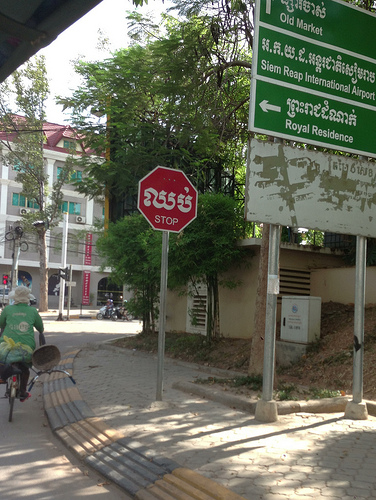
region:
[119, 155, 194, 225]
red and white sign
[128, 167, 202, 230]
white characters on sign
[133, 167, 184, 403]
sign on grey pole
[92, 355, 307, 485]
sidewalk is light grey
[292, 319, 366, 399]
light brown mulch on hill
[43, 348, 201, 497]
grey and yellow curb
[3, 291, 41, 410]
man is on bike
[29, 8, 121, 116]
grey and bright sky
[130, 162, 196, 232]
red and white sign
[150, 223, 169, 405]
stop sign on steel pole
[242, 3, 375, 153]
green and white sign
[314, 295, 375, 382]
brown mulch on hill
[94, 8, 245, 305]
green tree behind stop sign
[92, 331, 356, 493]
sidewalk is light grey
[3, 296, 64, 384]
man is on bike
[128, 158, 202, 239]
The sign is red and white.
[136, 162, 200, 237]
The sign is octagonal.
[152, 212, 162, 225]
The letter is white.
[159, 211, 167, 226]
The letter is white.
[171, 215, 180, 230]
The letter is white.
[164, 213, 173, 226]
The letter is white.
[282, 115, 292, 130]
The letter is white.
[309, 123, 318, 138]
The letter is white.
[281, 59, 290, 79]
The letter is white.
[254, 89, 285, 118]
The arrow is white.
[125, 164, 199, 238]
red and white sign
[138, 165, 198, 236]
white characters on sign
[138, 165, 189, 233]
red sign is octagonal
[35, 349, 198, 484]
yellow and grey curb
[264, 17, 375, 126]
green and white sign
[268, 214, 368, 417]
sign on metal posts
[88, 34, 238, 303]
green tree behind stop sign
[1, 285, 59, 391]
person is on bike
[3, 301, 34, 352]
man has green shirt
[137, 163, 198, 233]
stop sign has a white border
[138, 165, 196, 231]
stop sign is attached to a pole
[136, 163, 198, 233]
stop sign is in the shape of an octagon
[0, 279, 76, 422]
bicyclist is carrying another bike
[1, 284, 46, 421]
human is riding bicycle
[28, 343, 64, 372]
basket is attached to bicycle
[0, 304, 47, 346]
green top is worn by human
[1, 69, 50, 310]
tree is in background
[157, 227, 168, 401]
pole supports stop sign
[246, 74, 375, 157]
sign gives directions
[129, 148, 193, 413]
red sign on pole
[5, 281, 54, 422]
man riding a bicycle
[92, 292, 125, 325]
two people on a motorcycle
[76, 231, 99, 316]
red banner in front of building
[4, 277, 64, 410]
man wearing beige hat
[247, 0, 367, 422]
green sign on pole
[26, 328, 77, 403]
bicycle with wicker basket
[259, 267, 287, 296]
paper taped to pole